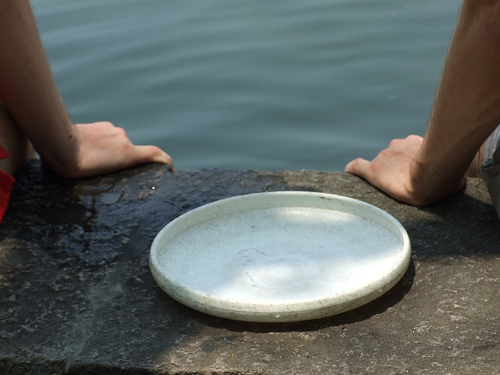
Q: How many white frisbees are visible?
A: One.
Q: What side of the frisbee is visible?
A: The underbelly.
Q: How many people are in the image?
A: Two.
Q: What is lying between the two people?
A: A frisbee.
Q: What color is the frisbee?
A: White.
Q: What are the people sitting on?
A: Concrete.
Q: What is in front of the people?
A: Water.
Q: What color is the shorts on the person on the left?
A: Orange.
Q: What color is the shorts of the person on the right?
A: Blue.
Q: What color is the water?
A: Greenish blue.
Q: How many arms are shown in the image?
A: Two.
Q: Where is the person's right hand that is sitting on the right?
A: On the rock bench.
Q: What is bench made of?
A: Rock.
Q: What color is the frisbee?
A: White.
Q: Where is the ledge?
A: On waterfront.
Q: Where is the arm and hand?
A: Edge of water.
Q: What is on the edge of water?
A: Arm and hand.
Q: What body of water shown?
A: Lake.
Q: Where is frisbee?
A: On ledge.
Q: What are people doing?
A: Sitting.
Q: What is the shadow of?
A: A person.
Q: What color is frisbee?
A: White.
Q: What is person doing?
A: Sitting.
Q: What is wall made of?
A: Stone.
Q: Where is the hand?
A: On rock.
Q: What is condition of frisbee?
A: Worn.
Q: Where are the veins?
A: On skin.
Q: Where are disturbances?
A: Water.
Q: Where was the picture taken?
A: By the water.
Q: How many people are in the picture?
A: Two.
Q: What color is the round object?
A: White.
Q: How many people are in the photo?
A: Two.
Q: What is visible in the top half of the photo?
A: Water.